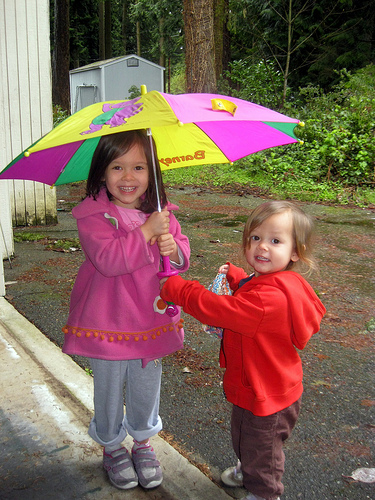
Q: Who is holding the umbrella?
A: Both children.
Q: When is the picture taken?
A: Daytime.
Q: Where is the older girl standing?
A: On the pavement.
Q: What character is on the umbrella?
A: Barney.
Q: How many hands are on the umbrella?
A: Three.